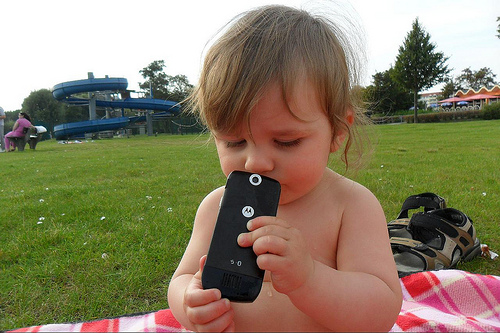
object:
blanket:
[2, 268, 499, 332]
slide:
[52, 77, 182, 140]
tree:
[386, 15, 452, 124]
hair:
[176, 1, 378, 181]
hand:
[237, 215, 314, 293]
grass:
[0, 119, 499, 332]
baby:
[165, 4, 403, 332]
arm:
[287, 185, 404, 332]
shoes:
[390, 206, 481, 277]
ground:
[0, 67, 499, 118]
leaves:
[425, 68, 430, 72]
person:
[3, 111, 32, 152]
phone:
[200, 170, 282, 304]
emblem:
[241, 204, 256, 218]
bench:
[6, 125, 48, 151]